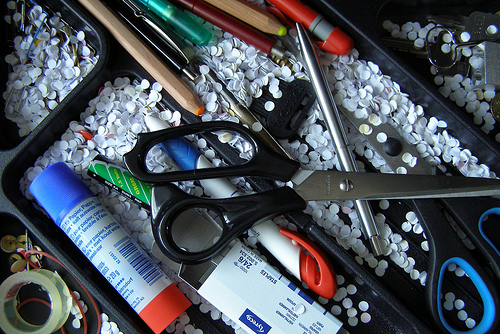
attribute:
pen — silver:
[293, 21, 392, 258]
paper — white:
[387, 86, 405, 98]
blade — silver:
[358, 177, 490, 203]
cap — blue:
[29, 161, 100, 229]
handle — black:
[109, 118, 312, 268]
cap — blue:
[11, 157, 101, 228]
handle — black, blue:
[435, 194, 499, 276]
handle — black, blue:
[408, 200, 499, 330]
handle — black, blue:
[153, 186, 308, 264]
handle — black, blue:
[123, 122, 301, 187]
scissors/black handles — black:
[122, 120, 499, 265]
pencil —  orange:
[77, 0, 209, 117]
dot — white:
[373, 130, 388, 143]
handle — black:
[166, 81, 315, 266]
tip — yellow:
[271, 22, 291, 38]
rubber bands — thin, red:
[4, 232, 138, 331]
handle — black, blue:
[442, 235, 497, 302]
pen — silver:
[295, 21, 381, 255]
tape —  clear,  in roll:
[1, 266, 72, 332]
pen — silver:
[273, 41, 392, 176]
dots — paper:
[1, 0, 498, 332]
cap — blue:
[32, 161, 93, 223]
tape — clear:
[6, 259, 72, 331]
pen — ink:
[145, 112, 335, 301]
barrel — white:
[232, 190, 305, 280]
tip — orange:
[195, 104, 205, 118]